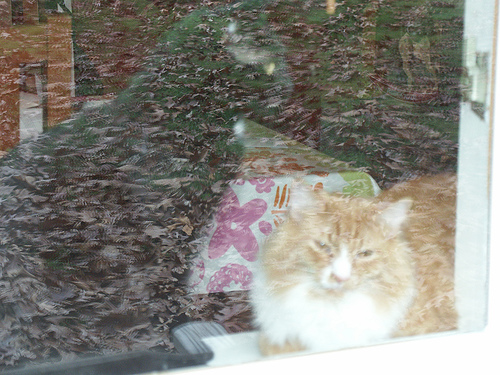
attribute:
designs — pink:
[205, 184, 275, 305]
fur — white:
[270, 287, 340, 344]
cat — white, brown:
[274, 180, 468, 324]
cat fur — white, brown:
[251, 179, 419, 351]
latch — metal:
[462, 56, 487, 118]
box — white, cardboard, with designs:
[163, 105, 397, 295]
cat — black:
[0, 17, 317, 347]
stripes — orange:
[327, 214, 362, 246]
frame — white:
[455, 0, 491, 374]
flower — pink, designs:
[206, 186, 268, 264]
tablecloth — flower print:
[187, 117, 382, 294]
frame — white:
[453, 2, 493, 346]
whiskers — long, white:
[284, 264, 399, 302]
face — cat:
[297, 194, 391, 294]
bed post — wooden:
[42, 12, 75, 128]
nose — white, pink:
[329, 269, 350, 283]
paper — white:
[186, 116, 383, 301]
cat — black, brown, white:
[251, 167, 462, 357]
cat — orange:
[245, 167, 460, 344]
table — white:
[203, 328, 265, 365]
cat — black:
[238, 170, 430, 360]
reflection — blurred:
[396, 16, 440, 94]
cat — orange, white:
[235, 174, 472, 359]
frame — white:
[453, 2, 489, 332]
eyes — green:
[308, 234, 383, 273]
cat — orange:
[252, 169, 450, 333]